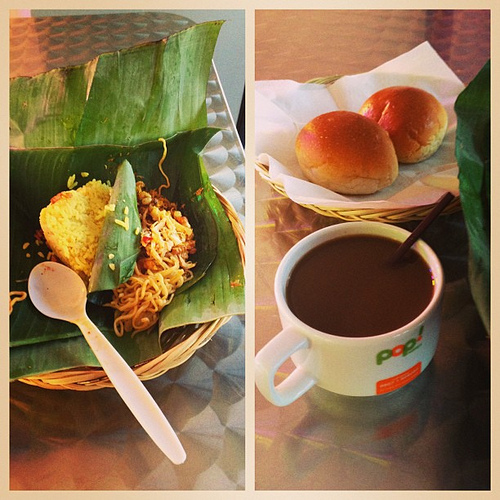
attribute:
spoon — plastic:
[28, 261, 186, 463]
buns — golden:
[298, 86, 450, 195]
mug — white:
[258, 221, 444, 411]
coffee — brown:
[300, 250, 420, 321]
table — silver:
[260, 426, 491, 492]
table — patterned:
[10, 18, 184, 36]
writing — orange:
[378, 363, 425, 395]